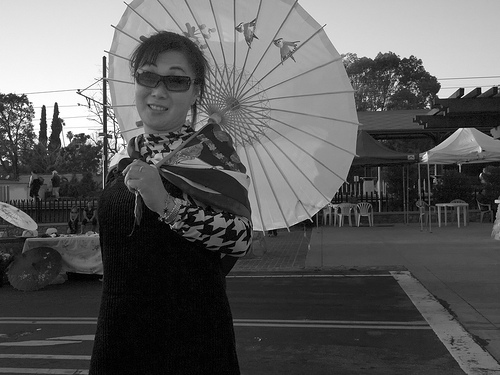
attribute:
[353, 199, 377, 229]
chair — lawn chair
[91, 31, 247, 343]
woman — houndstooth patterned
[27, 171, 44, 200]
animal — BROWN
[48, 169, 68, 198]
animal — BROWN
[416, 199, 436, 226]
chair — lawn chair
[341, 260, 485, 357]
paint — white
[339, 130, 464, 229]
animals — Two brown 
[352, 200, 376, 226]
plastic chairs — white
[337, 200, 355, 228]
plastic chairs — white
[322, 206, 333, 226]
plastic chairs — white